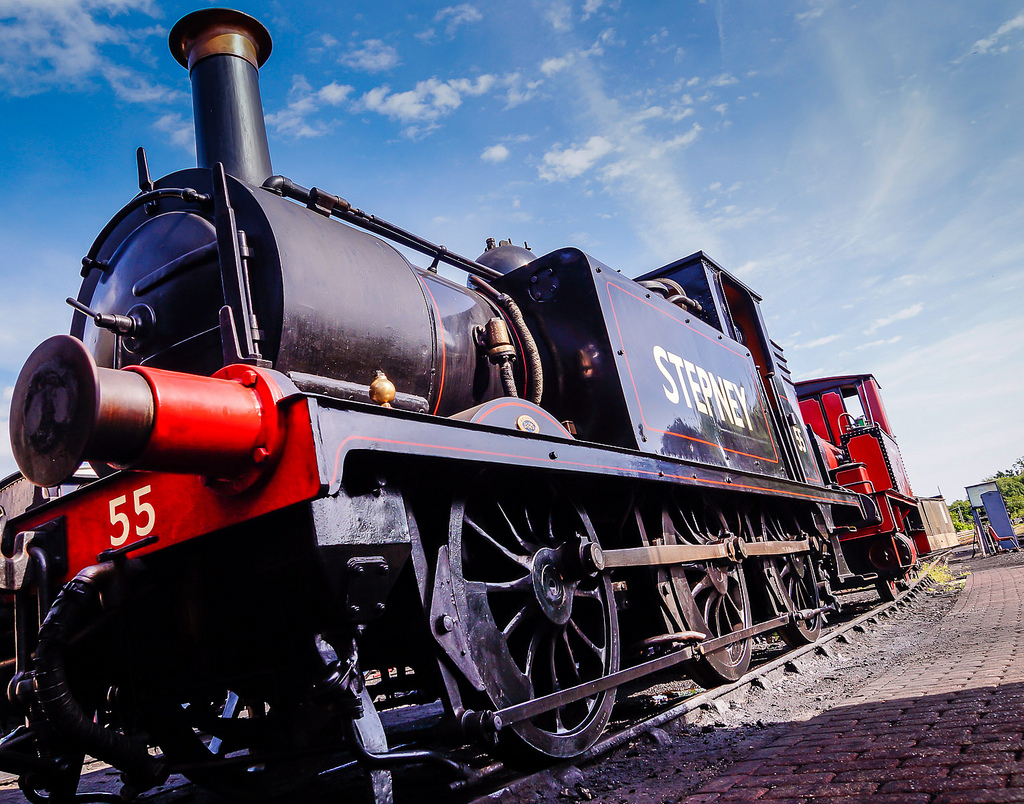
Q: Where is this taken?
A: At a train station.